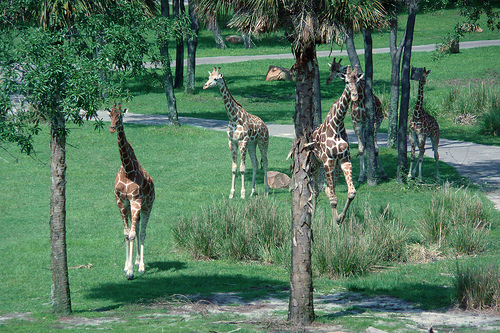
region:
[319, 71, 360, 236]
giraffe on the tree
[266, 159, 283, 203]
rock on the ground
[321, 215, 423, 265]
high grass on the lawn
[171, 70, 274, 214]
giraffe standing still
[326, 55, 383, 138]
giraffe behind the tree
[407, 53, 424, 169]
animal looking up at tree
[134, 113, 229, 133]
pavement behind the tree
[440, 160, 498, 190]
shadows on the pavement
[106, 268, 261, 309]
shadows from the trees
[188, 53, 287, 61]
road behind the area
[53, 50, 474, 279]
A group of giraffes.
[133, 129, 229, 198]
The grass is green.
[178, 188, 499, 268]
Patches of tall grass.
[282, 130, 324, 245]
Spikes growing on a tree.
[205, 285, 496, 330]
Dirt patches in the grass.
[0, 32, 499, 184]
There are two paved roads.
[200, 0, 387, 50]
The leaves are drying.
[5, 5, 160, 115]
The leaves are green.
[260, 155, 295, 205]
There is a rock.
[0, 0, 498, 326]
Taken in a zoo.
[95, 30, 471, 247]
the giraffes are walking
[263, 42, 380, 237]
the giraffe is brown and white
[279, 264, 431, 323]
shadow on the floor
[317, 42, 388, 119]
giraffe is looking at the camera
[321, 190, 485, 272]
the grass is tall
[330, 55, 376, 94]
the giraffe has horns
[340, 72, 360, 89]
the eyes are open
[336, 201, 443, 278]
the grass is green and tan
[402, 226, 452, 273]
the grass is dried out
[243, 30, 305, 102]
a rock in the background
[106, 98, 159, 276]
a giraffe in the park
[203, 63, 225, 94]
the head of a giraffe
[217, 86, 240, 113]
the neck of a giraffe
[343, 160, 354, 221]
the leg of a giraffe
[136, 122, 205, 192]
green lawn in the park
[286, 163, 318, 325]
the trunk of a tree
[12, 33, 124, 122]
green leaves of a tree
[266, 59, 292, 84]
a stone in the park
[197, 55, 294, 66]
a path in the park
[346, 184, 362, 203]
the knee of a giraffe